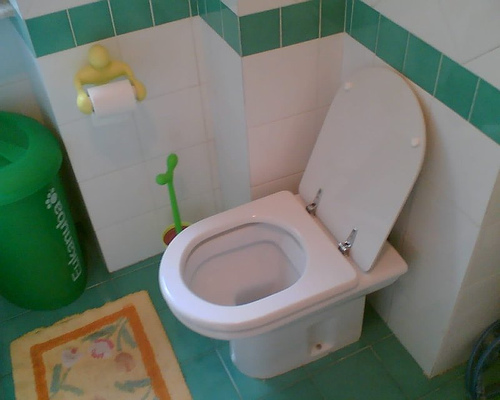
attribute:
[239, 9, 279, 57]
ceramic tile — square, green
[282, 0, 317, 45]
ceramic tile — square, green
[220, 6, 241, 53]
ceramic tile — square, green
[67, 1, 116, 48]
ceramic tile — square, green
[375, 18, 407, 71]
ceramic tile — square, green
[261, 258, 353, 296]
toilet seat — white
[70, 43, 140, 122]
holder — yellow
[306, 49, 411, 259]
lid — white, porcelain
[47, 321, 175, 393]
mat — decorative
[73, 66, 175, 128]
toilet paper — white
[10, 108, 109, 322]
container — green, plastic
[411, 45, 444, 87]
tile — green, white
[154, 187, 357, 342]
seat — white, porcelain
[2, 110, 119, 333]
can — green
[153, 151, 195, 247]
toilet plunger — decorative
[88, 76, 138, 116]
toilet paper — roll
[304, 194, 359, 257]
hardware — silver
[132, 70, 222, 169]
tile — square, white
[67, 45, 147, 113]
toilet-paper holder — yellow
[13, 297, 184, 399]
rug — small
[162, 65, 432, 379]
toilet — white, porcelain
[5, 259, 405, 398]
floor — green, tile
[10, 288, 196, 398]
rug — yellow, orange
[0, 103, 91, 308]
bin — plastic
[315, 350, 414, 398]
floor tile — green, porcelain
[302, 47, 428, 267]
lid — open